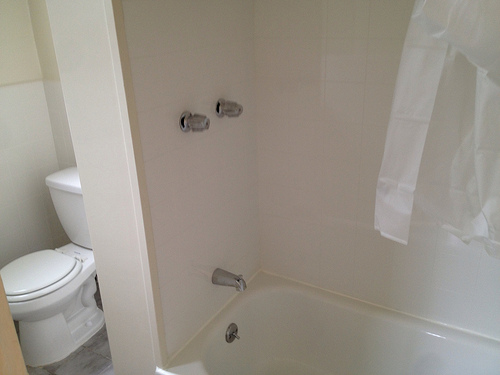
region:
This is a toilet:
[2, 150, 132, 374]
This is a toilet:
[15, 130, 172, 370]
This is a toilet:
[4, 146, 119, 361]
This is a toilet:
[6, 168, 351, 374]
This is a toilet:
[13, 165, 110, 345]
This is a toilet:
[8, 153, 119, 319]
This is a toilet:
[6, 156, 123, 369]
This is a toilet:
[6, 163, 182, 371]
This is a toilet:
[9, 148, 136, 368]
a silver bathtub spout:
[207, 265, 247, 293]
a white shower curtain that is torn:
[374, 0, 499, 256]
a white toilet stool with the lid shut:
[0, 163, 102, 365]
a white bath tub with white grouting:
[166, 268, 498, 374]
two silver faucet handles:
[177, 95, 244, 131]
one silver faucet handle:
[179, 109, 211, 131]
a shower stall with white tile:
[121, 3, 498, 373]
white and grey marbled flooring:
[25, 329, 110, 374]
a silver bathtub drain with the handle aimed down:
[222, 319, 240, 343]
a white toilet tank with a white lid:
[45, 162, 96, 248]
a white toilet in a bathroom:
[0, 167, 103, 367]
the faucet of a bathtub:
[210, 267, 249, 295]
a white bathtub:
[158, 267, 499, 372]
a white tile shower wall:
[251, 2, 499, 341]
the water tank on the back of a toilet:
[44, 166, 93, 249]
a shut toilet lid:
[1, 248, 75, 295]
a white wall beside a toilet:
[1, 80, 63, 266]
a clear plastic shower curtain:
[372, 1, 498, 253]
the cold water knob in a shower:
[215, 97, 245, 119]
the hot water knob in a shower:
[179, 110, 212, 135]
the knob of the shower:
[185, 113, 210, 133]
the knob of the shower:
[217, 98, 242, 115]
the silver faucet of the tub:
[212, 268, 248, 294]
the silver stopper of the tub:
[225, 324, 239, 343]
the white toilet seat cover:
[2, 247, 73, 295]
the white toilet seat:
[2, 261, 87, 304]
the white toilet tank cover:
[45, 168, 81, 190]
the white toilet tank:
[46, 167, 94, 244]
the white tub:
[170, 267, 493, 372]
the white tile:
[50, 344, 116, 374]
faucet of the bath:
[172, 250, 242, 286]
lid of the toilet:
[0, 220, 48, 311]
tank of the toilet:
[39, 150, 86, 200]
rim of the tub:
[208, 289, 477, 373]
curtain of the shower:
[388, 1, 492, 248]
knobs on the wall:
[167, 63, 244, 146]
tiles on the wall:
[17, 37, 47, 147]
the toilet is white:
[40, 325, 83, 349]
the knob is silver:
[182, 115, 209, 127]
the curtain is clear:
[405, 30, 490, 182]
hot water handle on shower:
[182, 101, 214, 144]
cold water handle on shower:
[220, 98, 245, 123]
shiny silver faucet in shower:
[213, 251, 260, 300]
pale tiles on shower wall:
[167, 185, 205, 215]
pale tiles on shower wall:
[331, 201, 353, 228]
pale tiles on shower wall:
[306, 106, 329, 134]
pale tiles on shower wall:
[330, 71, 357, 92]